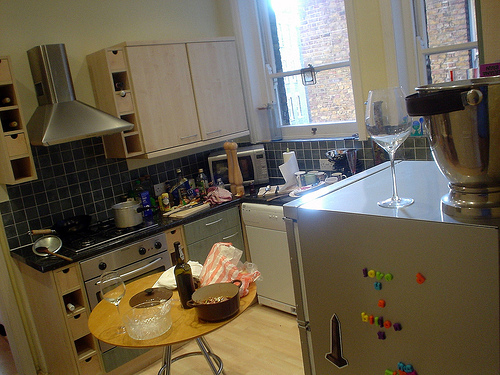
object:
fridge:
[283, 159, 497, 375]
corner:
[207, 136, 275, 198]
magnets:
[383, 360, 418, 375]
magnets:
[359, 311, 403, 340]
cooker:
[111, 201, 156, 229]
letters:
[359, 268, 425, 375]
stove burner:
[106, 223, 143, 237]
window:
[263, 0, 356, 125]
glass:
[364, 85, 415, 208]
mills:
[223, 142, 245, 197]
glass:
[100, 271, 127, 334]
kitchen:
[1, 0, 500, 375]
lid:
[186, 280, 243, 323]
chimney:
[25, 43, 136, 147]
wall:
[0, 0, 228, 117]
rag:
[202, 186, 233, 205]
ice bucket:
[405, 75, 500, 225]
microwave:
[208, 144, 270, 190]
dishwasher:
[241, 202, 297, 317]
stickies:
[416, 272, 426, 284]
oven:
[60, 219, 173, 374]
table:
[87, 271, 257, 375]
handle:
[403, 88, 467, 117]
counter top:
[8, 183, 304, 274]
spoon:
[35, 247, 73, 263]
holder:
[279, 151, 300, 183]